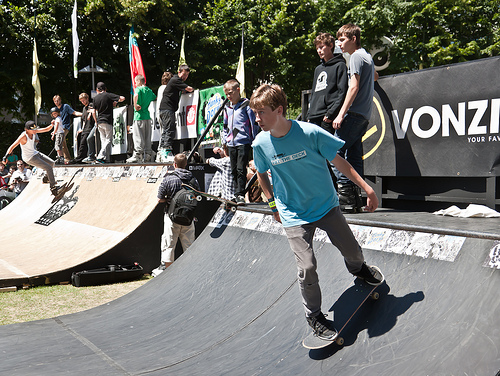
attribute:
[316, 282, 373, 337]
skateboard — black, tan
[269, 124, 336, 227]
shirt — turquoise, blue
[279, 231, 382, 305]
pants — khaki, gray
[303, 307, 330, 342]
shoes — black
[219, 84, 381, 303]
boy — skateboarding, young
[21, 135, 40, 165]
tank top — white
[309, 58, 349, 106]
pullover — black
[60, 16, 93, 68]
flag — american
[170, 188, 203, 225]
backpack — black, worn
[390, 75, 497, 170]
advertisement — promotional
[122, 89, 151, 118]
tshirt — green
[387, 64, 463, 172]
wall — black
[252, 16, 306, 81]
tree — green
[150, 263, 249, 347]
ramp — black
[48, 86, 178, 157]
people — standing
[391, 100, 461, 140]
logo — white